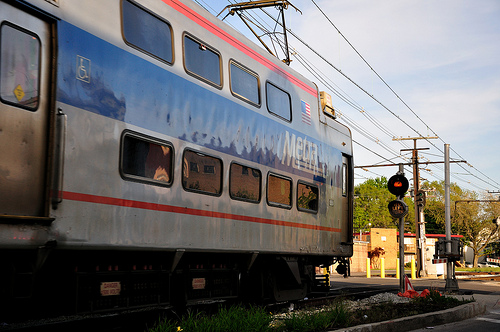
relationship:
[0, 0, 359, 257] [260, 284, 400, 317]
train of tracks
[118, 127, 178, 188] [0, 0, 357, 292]
window on side of train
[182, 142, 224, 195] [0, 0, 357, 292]
window on side of train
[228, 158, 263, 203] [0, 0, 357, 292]
window on side of train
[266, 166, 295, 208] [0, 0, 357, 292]
window on side of train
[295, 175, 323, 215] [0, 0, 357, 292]
window on side of train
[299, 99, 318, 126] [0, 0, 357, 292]
flag on side of train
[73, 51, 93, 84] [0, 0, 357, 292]
sign on side of train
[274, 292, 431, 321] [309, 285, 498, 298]
rocks on side of tracks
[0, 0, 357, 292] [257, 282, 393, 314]
train on tracks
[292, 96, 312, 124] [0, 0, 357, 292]
flag on train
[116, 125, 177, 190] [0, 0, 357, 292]
window on train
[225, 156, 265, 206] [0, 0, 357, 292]
window on train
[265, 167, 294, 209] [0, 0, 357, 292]
window on train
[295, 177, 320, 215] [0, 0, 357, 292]
window on train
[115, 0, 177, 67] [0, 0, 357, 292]
window on train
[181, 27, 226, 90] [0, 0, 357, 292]
window on train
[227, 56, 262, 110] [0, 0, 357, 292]
window on train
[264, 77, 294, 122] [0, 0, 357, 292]
window on train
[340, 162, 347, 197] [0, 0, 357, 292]
window on train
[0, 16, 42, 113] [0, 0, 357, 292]
window on train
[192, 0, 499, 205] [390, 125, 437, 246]
wires connected to poles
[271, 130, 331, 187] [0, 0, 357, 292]
logo painted on train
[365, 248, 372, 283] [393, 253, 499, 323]
post on concrete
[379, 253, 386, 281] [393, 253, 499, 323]
post on concrete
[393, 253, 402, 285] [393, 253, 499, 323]
post on concrete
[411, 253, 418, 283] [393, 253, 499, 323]
post on concrete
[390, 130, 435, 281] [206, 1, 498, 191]
post holding up power lines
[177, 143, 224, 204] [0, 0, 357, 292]
window on train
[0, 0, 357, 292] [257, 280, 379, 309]
train traveling on tracks